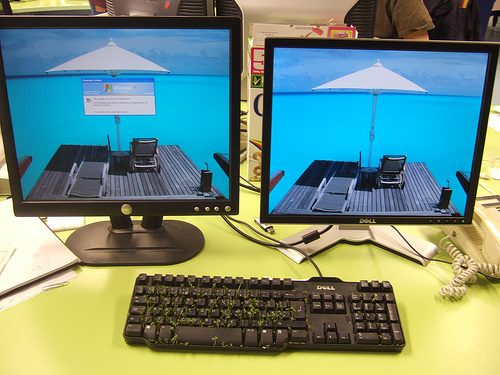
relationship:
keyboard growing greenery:
[122, 272, 405, 353] [150, 290, 293, 323]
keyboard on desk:
[122, 272, 405, 353] [2, 129, 498, 372]